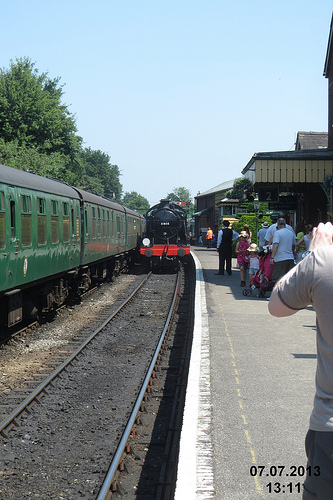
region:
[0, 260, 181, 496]
a set of train tracks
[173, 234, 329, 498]
a train boarding platform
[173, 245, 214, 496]
a long white painted stripe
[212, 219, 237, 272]
a man standing on platform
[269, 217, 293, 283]
a man standing on platform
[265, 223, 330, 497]
a man standing on platform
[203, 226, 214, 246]
a man standing on platform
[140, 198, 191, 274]
a black and red train engine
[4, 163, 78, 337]
a green passenger train car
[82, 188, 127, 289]
a green passenger train car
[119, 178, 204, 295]
a black and red train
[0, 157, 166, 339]
a green long train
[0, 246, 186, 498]
a silver track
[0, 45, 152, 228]
a green row trees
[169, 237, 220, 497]
a white line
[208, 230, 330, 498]
a gray sidewalk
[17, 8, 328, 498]
a scene outside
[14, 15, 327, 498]
a scene during the day time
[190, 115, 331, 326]
a train station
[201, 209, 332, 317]
a group of people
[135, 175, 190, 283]
the train on the tracks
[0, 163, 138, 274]
the opposite train on the tracks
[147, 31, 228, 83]
the clear blue sky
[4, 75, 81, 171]
the trees with green leaves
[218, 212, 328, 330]
the people on the platform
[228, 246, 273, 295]
the stroller on the platform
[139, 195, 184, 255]
the train is red and black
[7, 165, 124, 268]
the train is green and black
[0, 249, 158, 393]
the gravel beside the tracks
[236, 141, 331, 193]
the awning over the platform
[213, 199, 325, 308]
several people standing at a train station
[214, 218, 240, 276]
a man wearing a black conductor's outfit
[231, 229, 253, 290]
a girl wearing a pink outfit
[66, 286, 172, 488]
the rails of a train track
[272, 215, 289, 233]
the back of a man's head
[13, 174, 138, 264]
the cars on a green passenger train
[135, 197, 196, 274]
the front of a black locomotive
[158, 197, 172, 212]
the smokestack on a locomotive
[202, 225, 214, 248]
a man wearing an orange vest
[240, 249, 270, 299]
a pink baby stroller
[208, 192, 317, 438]
people at the platform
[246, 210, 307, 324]
people at the platform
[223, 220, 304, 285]
people at the platform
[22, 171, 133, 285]
the train is green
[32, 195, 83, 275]
the train is green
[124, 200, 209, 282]
the train is black